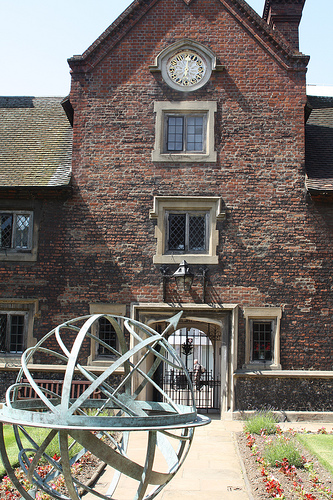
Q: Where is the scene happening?
A: At an old country house.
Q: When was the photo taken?
A: At noon.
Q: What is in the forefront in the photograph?
A: A metal sculpture.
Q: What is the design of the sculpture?
A: A spherical shape with an arrow through it.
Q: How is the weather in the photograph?
A: Crisp and sunny.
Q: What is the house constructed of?
A: Bricks.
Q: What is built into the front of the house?
A: A clock.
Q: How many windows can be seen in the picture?
A: 6.